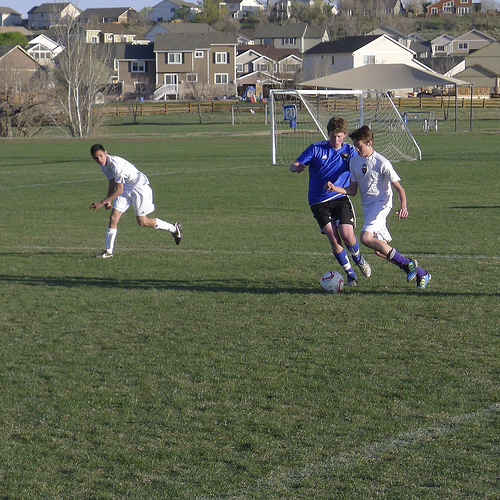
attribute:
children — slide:
[78, 113, 436, 297]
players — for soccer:
[322, 125, 437, 288]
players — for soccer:
[291, 105, 373, 286]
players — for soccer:
[80, 137, 185, 257]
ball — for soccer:
[308, 270, 349, 296]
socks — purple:
[387, 251, 407, 268]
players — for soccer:
[90, 142, 180, 258]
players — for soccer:
[350, 126, 429, 286]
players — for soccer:
[292, 115, 371, 277]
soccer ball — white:
[317, 272, 346, 294]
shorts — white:
[361, 205, 393, 240]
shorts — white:
[112, 184, 153, 216]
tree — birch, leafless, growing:
[16, 23, 138, 148]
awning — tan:
[301, 60, 472, 132]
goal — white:
[236, 69, 431, 181]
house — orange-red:
[427, 6, 474, 22]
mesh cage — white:
[276, 83, 398, 149]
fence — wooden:
[402, 96, 483, 108]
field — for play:
[0, 112, 497, 497]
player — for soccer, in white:
[81, 141, 181, 259]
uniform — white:
[101, 151, 154, 214]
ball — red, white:
[308, 248, 355, 303]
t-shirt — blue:
[293, 134, 358, 200]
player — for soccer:
[284, 110, 374, 294]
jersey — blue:
[289, 141, 356, 208]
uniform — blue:
[297, 139, 359, 206]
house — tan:
[149, 24, 239, 103]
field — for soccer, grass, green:
[252, 173, 304, 197]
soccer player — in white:
[88, 137, 186, 260]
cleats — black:
[173, 221, 190, 242]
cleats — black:
[94, 253, 115, 266]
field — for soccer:
[3, 146, 499, 500]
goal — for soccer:
[266, 83, 422, 171]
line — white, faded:
[220, 393, 495, 500]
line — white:
[6, 237, 498, 259]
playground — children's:
[246, 72, 268, 109]